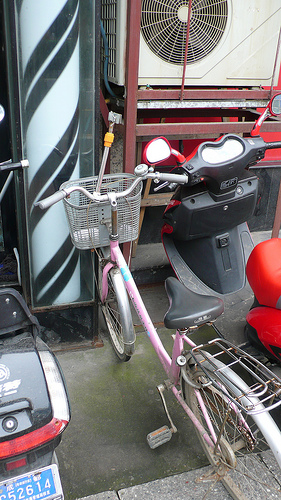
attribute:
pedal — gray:
[141, 423, 180, 452]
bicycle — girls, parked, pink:
[33, 159, 279, 497]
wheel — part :
[95, 260, 132, 366]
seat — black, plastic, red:
[147, 267, 230, 331]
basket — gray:
[57, 172, 142, 250]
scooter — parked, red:
[130, 90, 280, 375]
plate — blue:
[0, 459, 77, 496]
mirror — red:
[137, 133, 175, 167]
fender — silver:
[195, 346, 279, 411]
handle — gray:
[142, 172, 188, 186]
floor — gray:
[60, 273, 204, 487]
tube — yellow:
[102, 133, 116, 146]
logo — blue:
[222, 172, 238, 192]